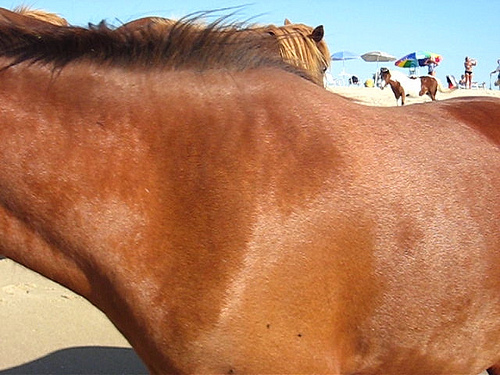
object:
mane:
[0, 2, 328, 91]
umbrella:
[395, 50, 443, 78]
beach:
[1, 83, 499, 375]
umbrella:
[361, 51, 397, 89]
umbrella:
[329, 51, 359, 82]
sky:
[0, 1, 499, 87]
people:
[422, 55, 439, 92]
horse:
[418, 75, 438, 102]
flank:
[0, 8, 499, 374]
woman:
[463, 56, 476, 88]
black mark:
[297, 332, 302, 338]